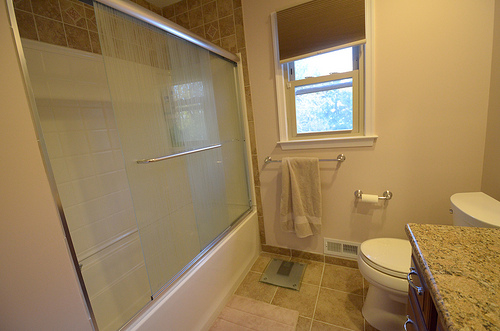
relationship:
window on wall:
[271, 0, 377, 150] [166, 1, 494, 269]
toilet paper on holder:
[360, 193, 377, 204] [353, 189, 391, 202]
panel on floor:
[260, 256, 308, 291] [198, 252, 372, 330]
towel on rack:
[279, 156, 323, 240] [262, 156, 345, 165]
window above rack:
[271, 0, 377, 150] [262, 156, 345, 165]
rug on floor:
[201, 293, 301, 330] [198, 252, 372, 330]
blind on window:
[276, 1, 367, 66] [271, 0, 377, 150]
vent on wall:
[323, 238, 359, 261] [166, 1, 494, 269]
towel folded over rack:
[279, 156, 323, 240] [262, 156, 345, 165]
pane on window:
[293, 78, 353, 134] [271, 0, 377, 150]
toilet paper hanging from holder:
[360, 193, 377, 204] [353, 189, 391, 202]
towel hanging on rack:
[279, 156, 323, 240] [262, 156, 345, 165]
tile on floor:
[310, 285, 366, 330] [198, 252, 372, 330]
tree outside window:
[293, 78, 353, 134] [271, 0, 377, 150]